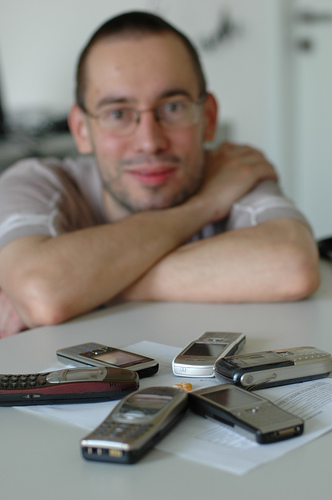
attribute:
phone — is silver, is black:
[187, 381, 306, 436]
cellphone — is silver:
[169, 318, 251, 385]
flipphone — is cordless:
[211, 343, 331, 388]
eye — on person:
[101, 102, 137, 132]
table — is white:
[10, 423, 60, 475]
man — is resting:
[2, 1, 331, 314]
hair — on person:
[76, 10, 205, 113]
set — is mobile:
[223, 343, 330, 385]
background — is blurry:
[0, 0, 329, 235]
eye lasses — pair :
[71, 89, 211, 134]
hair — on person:
[60, 2, 215, 113]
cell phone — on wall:
[31, 355, 197, 496]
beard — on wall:
[100, 151, 199, 210]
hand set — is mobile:
[187, 381, 303, 443]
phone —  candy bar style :
[173, 331, 246, 375]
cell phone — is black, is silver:
[81, 380, 189, 463]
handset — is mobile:
[81, 383, 187, 464]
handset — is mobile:
[187, 381, 304, 443]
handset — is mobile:
[216, 344, 328, 387]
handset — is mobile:
[170, 327, 245, 377]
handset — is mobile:
[57, 341, 160, 379]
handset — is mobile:
[0, 364, 140, 403]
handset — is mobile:
[0, 369, 141, 402]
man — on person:
[2, 6, 321, 334]